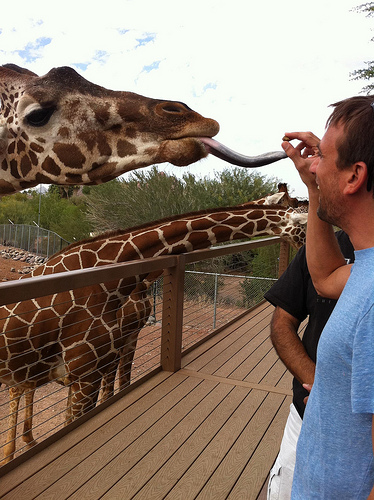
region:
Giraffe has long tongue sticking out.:
[210, 131, 297, 181]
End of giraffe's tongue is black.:
[225, 131, 305, 194]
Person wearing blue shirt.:
[319, 389, 342, 445]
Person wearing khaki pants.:
[268, 411, 302, 491]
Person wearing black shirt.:
[281, 277, 315, 341]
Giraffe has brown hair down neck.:
[45, 240, 125, 252]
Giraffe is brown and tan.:
[37, 260, 111, 372]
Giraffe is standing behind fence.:
[66, 248, 131, 327]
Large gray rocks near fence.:
[15, 240, 39, 269]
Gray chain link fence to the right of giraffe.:
[203, 269, 237, 342]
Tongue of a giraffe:
[193, 123, 294, 177]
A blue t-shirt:
[296, 239, 372, 492]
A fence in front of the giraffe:
[3, 235, 292, 485]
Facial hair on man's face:
[305, 167, 357, 234]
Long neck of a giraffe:
[117, 193, 292, 269]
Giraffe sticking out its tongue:
[2, 53, 287, 196]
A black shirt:
[261, 228, 360, 415]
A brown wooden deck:
[2, 273, 333, 498]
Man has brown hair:
[297, 93, 373, 191]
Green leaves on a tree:
[48, 201, 81, 228]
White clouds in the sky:
[88, 21, 239, 74]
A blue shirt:
[289, 241, 372, 495]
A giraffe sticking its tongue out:
[2, 56, 288, 205]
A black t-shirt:
[265, 229, 362, 416]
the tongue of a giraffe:
[211, 141, 286, 165]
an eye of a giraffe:
[17, 100, 56, 135]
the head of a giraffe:
[8, 73, 228, 203]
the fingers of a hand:
[273, 127, 312, 165]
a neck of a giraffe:
[103, 201, 291, 254]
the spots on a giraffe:
[42, 307, 111, 360]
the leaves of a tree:
[126, 183, 156, 212]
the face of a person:
[302, 120, 340, 216]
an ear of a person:
[338, 152, 368, 209]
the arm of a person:
[266, 281, 310, 389]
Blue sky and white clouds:
[12, 8, 202, 67]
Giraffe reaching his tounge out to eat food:
[0, 64, 292, 192]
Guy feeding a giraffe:
[286, 91, 372, 366]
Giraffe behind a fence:
[1, 174, 307, 368]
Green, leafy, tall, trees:
[18, 184, 191, 226]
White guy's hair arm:
[272, 304, 317, 388]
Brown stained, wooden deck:
[118, 369, 285, 458]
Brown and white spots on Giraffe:
[187, 204, 255, 240]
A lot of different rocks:
[0, 245, 40, 268]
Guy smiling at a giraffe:
[294, 99, 371, 235]